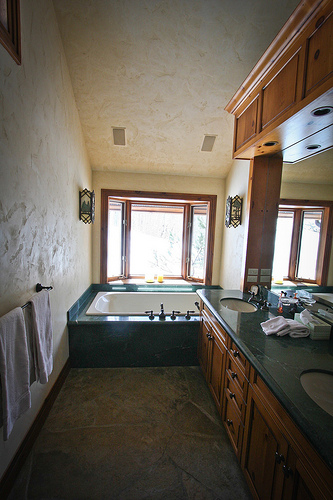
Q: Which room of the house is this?
A: It is a bathroom.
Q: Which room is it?
A: It is a bathroom.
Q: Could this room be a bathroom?
A: Yes, it is a bathroom.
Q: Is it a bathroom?
A: Yes, it is a bathroom.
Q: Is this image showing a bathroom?
A: Yes, it is showing a bathroom.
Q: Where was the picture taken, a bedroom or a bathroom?
A: It was taken at a bathroom.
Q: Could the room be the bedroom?
A: No, it is the bathroom.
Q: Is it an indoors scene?
A: Yes, it is indoors.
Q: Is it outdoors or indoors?
A: It is indoors.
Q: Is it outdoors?
A: No, it is indoors.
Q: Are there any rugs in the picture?
A: No, there are no rugs.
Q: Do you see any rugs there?
A: No, there are no rugs.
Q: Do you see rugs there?
A: No, there are no rugs.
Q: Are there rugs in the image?
A: No, there are no rugs.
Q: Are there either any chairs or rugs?
A: No, there are no rugs or chairs.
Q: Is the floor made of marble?
A: Yes, the floor is made of marble.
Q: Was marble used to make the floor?
A: Yes, the floor is made of marble.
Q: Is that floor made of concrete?
A: No, the floor is made of marble.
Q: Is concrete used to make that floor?
A: No, the floor is made of marble.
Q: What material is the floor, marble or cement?
A: The floor is made of marble.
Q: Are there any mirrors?
A: Yes, there is a mirror.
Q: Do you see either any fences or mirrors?
A: Yes, there is a mirror.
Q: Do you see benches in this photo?
A: No, there are no benches.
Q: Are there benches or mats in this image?
A: No, there are no benches or mats.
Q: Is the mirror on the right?
A: Yes, the mirror is on the right of the image.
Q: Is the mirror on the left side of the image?
A: No, the mirror is on the right of the image.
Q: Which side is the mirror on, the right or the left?
A: The mirror is on the right of the image.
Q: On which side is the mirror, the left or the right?
A: The mirror is on the right of the image.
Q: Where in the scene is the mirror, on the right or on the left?
A: The mirror is on the right of the image.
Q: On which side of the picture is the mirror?
A: The mirror is on the right of the image.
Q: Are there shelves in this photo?
A: No, there are no shelves.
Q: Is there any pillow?
A: No, there are no pillows.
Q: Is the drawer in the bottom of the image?
A: Yes, the drawer is in the bottom of the image.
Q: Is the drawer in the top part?
A: No, the drawer is in the bottom of the image.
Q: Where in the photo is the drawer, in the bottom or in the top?
A: The drawer is in the bottom of the image.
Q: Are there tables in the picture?
A: No, there are no tables.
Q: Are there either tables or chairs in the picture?
A: No, there are no tables or chairs.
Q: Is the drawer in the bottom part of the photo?
A: Yes, the drawer is in the bottom of the image.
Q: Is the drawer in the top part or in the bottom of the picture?
A: The drawer is in the bottom of the image.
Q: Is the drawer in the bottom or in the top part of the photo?
A: The drawer is in the bottom of the image.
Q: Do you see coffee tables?
A: No, there are no coffee tables.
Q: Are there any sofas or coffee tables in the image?
A: No, there are no coffee tables or sofas.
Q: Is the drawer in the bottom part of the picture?
A: Yes, the drawer is in the bottom of the image.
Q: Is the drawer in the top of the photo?
A: No, the drawer is in the bottom of the image.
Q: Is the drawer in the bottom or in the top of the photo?
A: The drawer is in the bottom of the image.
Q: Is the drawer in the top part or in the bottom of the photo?
A: The drawer is in the bottom of the image.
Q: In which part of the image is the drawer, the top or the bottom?
A: The drawer is in the bottom of the image.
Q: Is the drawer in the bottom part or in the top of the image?
A: The drawer is in the bottom of the image.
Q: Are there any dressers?
A: No, there are no dressers.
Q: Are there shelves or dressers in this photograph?
A: No, there are no dressers or shelves.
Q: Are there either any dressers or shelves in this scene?
A: No, there are no dressers or shelves.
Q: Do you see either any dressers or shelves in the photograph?
A: No, there are no dressers or shelves.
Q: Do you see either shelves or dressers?
A: No, there are no dressers or shelves.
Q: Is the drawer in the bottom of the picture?
A: Yes, the drawer is in the bottom of the image.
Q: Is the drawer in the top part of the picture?
A: No, the drawer is in the bottom of the image.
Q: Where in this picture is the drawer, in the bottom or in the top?
A: The drawer is in the bottom of the image.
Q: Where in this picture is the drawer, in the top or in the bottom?
A: The drawer is in the bottom of the image.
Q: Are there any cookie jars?
A: No, there are no cookie jars.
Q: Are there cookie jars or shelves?
A: No, there are no cookie jars or shelves.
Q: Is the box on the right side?
A: Yes, the box is on the right of the image.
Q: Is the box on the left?
A: No, the box is on the right of the image.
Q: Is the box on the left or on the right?
A: The box is on the right of the image.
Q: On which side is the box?
A: The box is on the right of the image.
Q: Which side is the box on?
A: The box is on the right of the image.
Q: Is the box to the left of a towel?
A: No, the box is to the right of a towel.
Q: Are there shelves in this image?
A: No, there are no shelves.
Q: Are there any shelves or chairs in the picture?
A: No, there are no shelves or chairs.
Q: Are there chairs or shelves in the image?
A: No, there are no shelves or chairs.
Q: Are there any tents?
A: No, there are no tents.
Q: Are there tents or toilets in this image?
A: No, there are no tents or toilets.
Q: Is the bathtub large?
A: Yes, the bathtub is large.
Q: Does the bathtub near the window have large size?
A: Yes, the bath tub is large.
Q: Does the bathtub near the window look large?
A: Yes, the bath tub is large.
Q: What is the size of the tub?
A: The tub is large.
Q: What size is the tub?
A: The tub is large.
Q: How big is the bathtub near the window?
A: The bathtub is large.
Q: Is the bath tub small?
A: No, the bath tub is large.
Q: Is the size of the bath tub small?
A: No, the bath tub is large.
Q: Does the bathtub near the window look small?
A: No, the bathtub is large.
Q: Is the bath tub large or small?
A: The bath tub is large.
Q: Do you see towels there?
A: Yes, there is a towel.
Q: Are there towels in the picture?
A: Yes, there is a towel.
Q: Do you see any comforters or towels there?
A: Yes, there is a towel.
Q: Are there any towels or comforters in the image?
A: Yes, there is a towel.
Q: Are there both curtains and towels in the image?
A: No, there is a towel but no curtains.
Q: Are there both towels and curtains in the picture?
A: No, there is a towel but no curtains.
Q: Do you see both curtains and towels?
A: No, there is a towel but no curtains.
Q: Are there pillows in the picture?
A: No, there are no pillows.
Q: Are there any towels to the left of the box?
A: Yes, there is a towel to the left of the box.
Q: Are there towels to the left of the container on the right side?
A: Yes, there is a towel to the left of the box.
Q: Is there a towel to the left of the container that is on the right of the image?
A: Yes, there is a towel to the left of the box.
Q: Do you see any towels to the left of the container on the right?
A: Yes, there is a towel to the left of the box.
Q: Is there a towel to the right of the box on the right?
A: No, the towel is to the left of the box.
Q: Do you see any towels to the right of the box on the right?
A: No, the towel is to the left of the box.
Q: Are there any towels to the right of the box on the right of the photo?
A: No, the towel is to the left of the box.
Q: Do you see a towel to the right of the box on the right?
A: No, the towel is to the left of the box.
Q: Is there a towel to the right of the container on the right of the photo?
A: No, the towel is to the left of the box.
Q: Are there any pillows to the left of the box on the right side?
A: No, there is a towel to the left of the box.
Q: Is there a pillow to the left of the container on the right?
A: No, there is a towel to the left of the box.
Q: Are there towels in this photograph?
A: Yes, there is a towel.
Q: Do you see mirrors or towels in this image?
A: Yes, there is a towel.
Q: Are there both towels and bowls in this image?
A: No, there is a towel but no bowls.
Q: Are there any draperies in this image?
A: No, there are no draperies.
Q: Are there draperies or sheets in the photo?
A: No, there are no draperies or sheets.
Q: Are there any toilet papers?
A: No, there are no toilet papers.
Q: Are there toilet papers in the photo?
A: No, there are no toilet papers.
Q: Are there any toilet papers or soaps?
A: No, there are no toilet papers or soaps.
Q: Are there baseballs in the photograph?
A: No, there are no baseballs.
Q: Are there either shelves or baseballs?
A: No, there are no baseballs or shelves.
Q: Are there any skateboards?
A: No, there are no skateboards.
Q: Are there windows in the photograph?
A: Yes, there is a window.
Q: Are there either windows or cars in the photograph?
A: Yes, there is a window.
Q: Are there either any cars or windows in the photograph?
A: Yes, there is a window.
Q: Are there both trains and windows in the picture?
A: No, there is a window but no trains.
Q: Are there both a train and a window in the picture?
A: No, there is a window but no trains.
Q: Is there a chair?
A: No, there are no chairs.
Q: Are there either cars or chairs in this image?
A: No, there are no chairs or cars.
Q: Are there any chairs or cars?
A: No, there are no chairs or cars.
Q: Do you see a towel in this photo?
A: Yes, there is a towel.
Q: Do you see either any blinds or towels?
A: Yes, there is a towel.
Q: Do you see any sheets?
A: No, there are no sheets.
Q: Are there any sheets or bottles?
A: No, there are no sheets or bottles.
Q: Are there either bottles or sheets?
A: No, there are no sheets or bottles.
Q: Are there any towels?
A: Yes, there is a towel.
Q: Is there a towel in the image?
A: Yes, there is a towel.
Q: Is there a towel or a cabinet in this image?
A: Yes, there is a towel.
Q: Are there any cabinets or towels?
A: Yes, there is a towel.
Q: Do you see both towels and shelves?
A: No, there is a towel but no shelves.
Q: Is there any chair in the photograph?
A: No, there are no chairs.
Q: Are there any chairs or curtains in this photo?
A: No, there are no chairs or curtains.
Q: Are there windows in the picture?
A: Yes, there is a window.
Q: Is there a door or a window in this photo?
A: Yes, there is a window.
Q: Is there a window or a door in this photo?
A: Yes, there is a window.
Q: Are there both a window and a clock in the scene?
A: No, there is a window but no clocks.